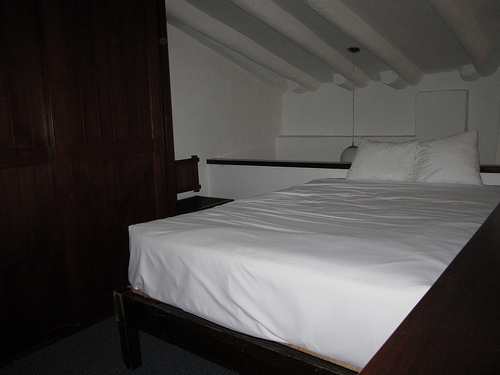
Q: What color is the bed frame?
A: Brown.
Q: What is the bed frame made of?
A: Wood.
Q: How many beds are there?
A: One.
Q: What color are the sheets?
A: White.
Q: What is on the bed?
A: Pillows.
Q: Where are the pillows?
A: On the bed.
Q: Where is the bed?
A: On the floor.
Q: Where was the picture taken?
A: In the loft.